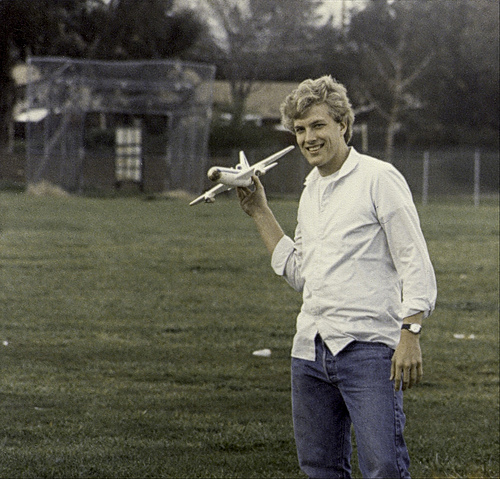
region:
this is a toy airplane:
[196, 154, 271, 189]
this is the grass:
[62, 219, 175, 414]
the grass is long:
[38, 230, 151, 407]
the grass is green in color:
[28, 242, 179, 456]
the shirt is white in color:
[328, 196, 382, 318]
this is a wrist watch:
[396, 315, 426, 334]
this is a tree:
[224, 0, 244, 151]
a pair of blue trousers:
[359, 377, 390, 458]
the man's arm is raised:
[253, 186, 293, 266]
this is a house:
[118, 71, 237, 103]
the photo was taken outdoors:
[7, 75, 494, 475]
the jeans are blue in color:
[270, 361, 399, 472]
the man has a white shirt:
[292, 216, 437, 327]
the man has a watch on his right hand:
[393, 313, 445, 345]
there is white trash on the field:
[216, 323, 276, 388]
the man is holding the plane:
[188, 153, 365, 217]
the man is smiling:
[284, 106, 363, 162]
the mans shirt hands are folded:
[253, 230, 344, 310]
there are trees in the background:
[135, 14, 497, 58]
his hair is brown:
[288, 81, 353, 133]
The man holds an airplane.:
[180, 69, 445, 477]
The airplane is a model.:
[172, 128, 312, 221]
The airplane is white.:
[170, 130, 307, 218]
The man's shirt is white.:
[255, 138, 452, 369]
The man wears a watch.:
[392, 317, 442, 342]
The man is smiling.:
[290, 136, 337, 158]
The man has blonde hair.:
[280, 67, 367, 138]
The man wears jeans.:
[286, 329, 423, 475]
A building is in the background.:
[0, 49, 377, 206]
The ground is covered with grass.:
[0, 241, 258, 477]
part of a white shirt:
[321, 214, 384, 281]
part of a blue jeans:
[349, 406, 394, 468]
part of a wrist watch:
[405, 326, 422, 337]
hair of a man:
[310, 85, 340, 98]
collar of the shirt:
[333, 162, 354, 181]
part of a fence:
[438, 160, 480, 193]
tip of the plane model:
[209, 167, 219, 184]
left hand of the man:
[394, 352, 420, 405]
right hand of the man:
[240, 181, 261, 230]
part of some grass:
[78, 310, 181, 430]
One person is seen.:
[196, 76, 443, 448]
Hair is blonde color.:
[291, 75, 331, 95]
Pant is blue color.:
[300, 380, 366, 445]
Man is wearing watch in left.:
[391, 320, 426, 337]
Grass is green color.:
[56, 330, 176, 450]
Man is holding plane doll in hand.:
[191, 127, 266, 203]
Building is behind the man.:
[0, 43, 285, 189]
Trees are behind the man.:
[30, 8, 455, 58]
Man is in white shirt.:
[300, 215, 382, 286]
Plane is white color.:
[202, 161, 261, 205]